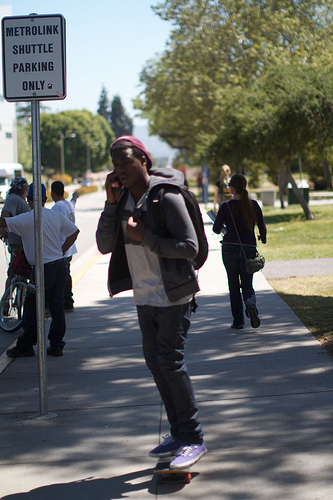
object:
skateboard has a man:
[153, 439, 199, 486]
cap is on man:
[107, 134, 155, 167]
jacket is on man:
[97, 164, 200, 301]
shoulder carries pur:
[224, 198, 266, 274]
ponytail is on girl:
[239, 186, 258, 231]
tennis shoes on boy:
[168, 439, 209, 470]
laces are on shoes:
[176, 444, 195, 459]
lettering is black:
[4, 24, 58, 90]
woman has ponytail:
[214, 164, 233, 214]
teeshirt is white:
[117, 195, 190, 306]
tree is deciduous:
[133, 2, 333, 222]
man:
[95, 135, 211, 461]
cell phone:
[107, 160, 122, 187]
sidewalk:
[3, 179, 279, 497]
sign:
[0, 16, 69, 108]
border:
[0, 11, 68, 101]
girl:
[209, 170, 269, 330]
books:
[206, 206, 228, 237]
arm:
[212, 202, 226, 234]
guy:
[0, 180, 79, 357]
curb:
[0, 336, 16, 372]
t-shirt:
[2, 204, 79, 263]